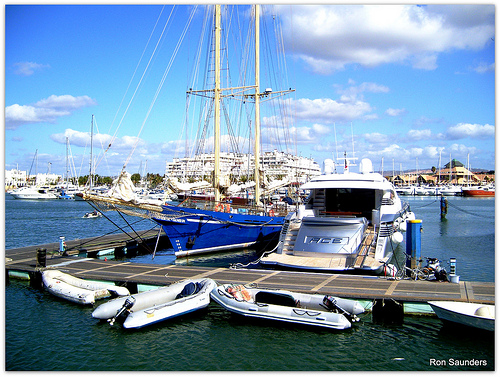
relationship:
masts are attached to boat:
[204, 3, 273, 217] [156, 205, 272, 248]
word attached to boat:
[297, 227, 348, 247] [281, 166, 413, 276]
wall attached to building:
[174, 166, 212, 180] [167, 147, 297, 188]